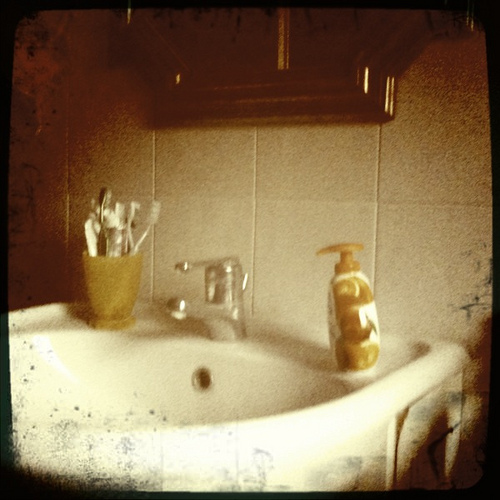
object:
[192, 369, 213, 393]
hole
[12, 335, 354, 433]
no water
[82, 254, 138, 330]
brushes glass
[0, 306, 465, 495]
bathroom sink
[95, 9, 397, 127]
picture frame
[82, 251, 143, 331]
cup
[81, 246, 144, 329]
toothbrush holder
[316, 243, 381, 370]
soap dispenser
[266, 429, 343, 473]
sink edge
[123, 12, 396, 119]
mirror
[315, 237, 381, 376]
dispenser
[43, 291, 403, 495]
wink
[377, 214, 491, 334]
tiles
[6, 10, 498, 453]
wall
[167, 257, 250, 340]
faucet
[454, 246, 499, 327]
marks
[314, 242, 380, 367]
soap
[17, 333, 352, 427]
sinkbowl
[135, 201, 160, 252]
toothbrush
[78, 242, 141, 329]
holder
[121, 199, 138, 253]
toothbrush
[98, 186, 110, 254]
toothbrush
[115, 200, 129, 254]
toothbrush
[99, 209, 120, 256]
toothbrush